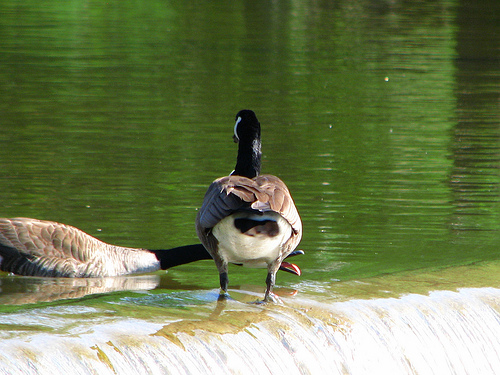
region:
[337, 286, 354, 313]
the water is green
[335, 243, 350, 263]
the water is green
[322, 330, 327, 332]
the water is green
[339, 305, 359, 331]
the water is green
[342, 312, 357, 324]
the water is green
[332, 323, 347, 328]
the water is green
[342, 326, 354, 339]
the water is green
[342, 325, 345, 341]
the water is green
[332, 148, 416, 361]
the water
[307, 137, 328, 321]
the water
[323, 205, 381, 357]
the water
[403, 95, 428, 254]
the water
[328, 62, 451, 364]
the water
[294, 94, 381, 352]
the water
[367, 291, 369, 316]
the water is green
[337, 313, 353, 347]
the water is green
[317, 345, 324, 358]
the water is green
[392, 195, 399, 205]
the water is green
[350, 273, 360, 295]
the water is green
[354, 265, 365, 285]
the water is green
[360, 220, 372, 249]
the water is green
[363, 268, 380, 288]
the water is green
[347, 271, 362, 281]
the water is green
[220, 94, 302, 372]
a duck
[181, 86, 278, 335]
a duck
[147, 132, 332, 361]
a duck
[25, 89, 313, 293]
Two geese in the water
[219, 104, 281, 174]
The goose has a black neck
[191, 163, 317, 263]
Brown and white feathers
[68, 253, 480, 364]
The water is flowing over the curb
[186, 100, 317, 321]
The goose is standing in the water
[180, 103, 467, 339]
The goose is standing on top of the cement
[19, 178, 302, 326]
The goose is in the water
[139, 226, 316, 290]
The goose has its mouth open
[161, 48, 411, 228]
The water is green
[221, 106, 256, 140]
The goose has a white mark on the side of its head